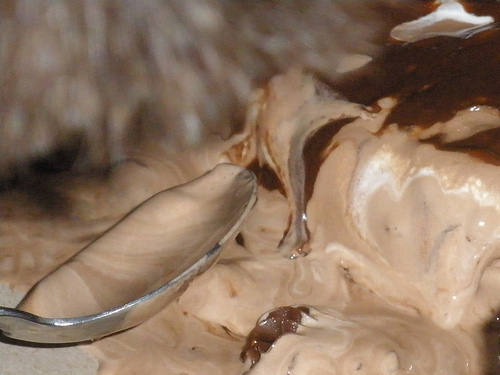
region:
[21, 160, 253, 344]
this is a spoon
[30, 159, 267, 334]
the spoon is covered with cream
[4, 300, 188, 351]
the spoon is on the cream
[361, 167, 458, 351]
the cream is pink in color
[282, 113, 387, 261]
the cream is moving downwards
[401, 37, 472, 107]
this is some chocolate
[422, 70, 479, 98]
the chocolate is brown in color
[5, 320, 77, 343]
the spoon is metallic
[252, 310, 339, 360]
chocolate covered in the cream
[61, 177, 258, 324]
oval side of the spoon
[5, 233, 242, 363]
silver spoon covered in brown dessert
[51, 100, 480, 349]
brown ice cream oozing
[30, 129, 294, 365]
spoon covered in chocolate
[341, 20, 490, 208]
dark brown on top of light brown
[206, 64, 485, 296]
light brown is under the dark brown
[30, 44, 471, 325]
dessert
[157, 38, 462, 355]
creamy chocolate dessert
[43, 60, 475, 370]
chocolate is dripping and melting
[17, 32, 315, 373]
the utensil is a spoon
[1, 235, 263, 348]
metal spoon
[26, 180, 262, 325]
the spoon is silver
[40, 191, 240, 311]
there is one spoon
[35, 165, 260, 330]
spoon in ice cream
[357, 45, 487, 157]
the syrup is hot fudge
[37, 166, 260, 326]
ice cream is on the spoon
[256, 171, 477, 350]
the ice cream is brown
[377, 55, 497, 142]
syrup is in the ice cream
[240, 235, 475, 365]
the ice cream is sweet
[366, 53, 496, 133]
the fudge is smooth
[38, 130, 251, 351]
spoon is made of silver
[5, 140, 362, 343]
Ice cream on spoon.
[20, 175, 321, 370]
Silver spoon with ice cream.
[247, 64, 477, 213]
Ice cream with swirls.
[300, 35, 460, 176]
Chocolate swirl in ice cream.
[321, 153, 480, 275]
Light part of ice cream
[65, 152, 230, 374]
Melting ice cream on spoon.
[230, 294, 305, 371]
Small section of chocolate.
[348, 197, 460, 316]
Vanilla ice cream.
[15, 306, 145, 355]
Metal spoon in ice cream.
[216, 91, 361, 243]
Ice cream swirled with chocolate and vanilla.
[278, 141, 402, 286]
Chocolate and vanilla melted ice cream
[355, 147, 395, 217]
vanilla ice cream that melted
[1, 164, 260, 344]
metal spoon with melted ice cream on it.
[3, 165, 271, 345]
metal spoon with melted ice cream on it.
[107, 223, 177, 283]
chocolate melted ice cream on a spoon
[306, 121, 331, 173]
dark chocolate fudge ice cream that is melted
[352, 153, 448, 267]
swirled around melted ice cream